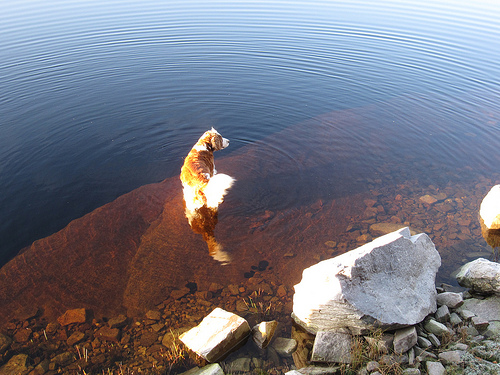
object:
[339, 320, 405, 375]
grass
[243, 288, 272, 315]
grass growing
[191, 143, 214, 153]
neck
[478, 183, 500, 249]
rock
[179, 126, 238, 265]
dog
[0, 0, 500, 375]
water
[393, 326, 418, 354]
stones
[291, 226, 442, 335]
rock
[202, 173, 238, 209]
tail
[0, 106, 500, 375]
ledge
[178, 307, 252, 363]
rock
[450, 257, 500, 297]
rock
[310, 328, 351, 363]
rock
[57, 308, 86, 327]
rock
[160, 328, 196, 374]
grass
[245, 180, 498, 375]
rocks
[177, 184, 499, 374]
shore